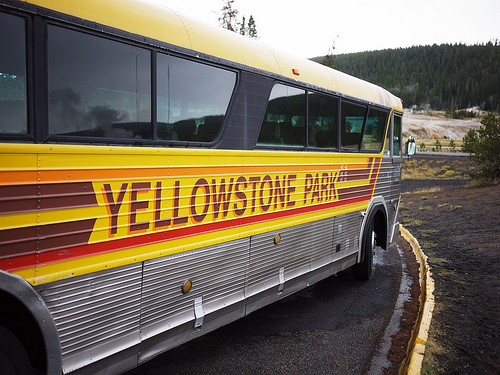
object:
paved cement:
[110, 237, 424, 374]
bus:
[0, 0, 419, 372]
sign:
[101, 170, 341, 235]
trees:
[243, 15, 257, 39]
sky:
[141, 0, 500, 60]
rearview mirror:
[408, 141, 415, 155]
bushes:
[478, 42, 498, 70]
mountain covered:
[307, 41, 500, 113]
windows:
[306, 89, 340, 151]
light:
[181, 278, 194, 295]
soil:
[396, 189, 500, 374]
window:
[47, 17, 154, 143]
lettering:
[96, 171, 342, 235]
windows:
[1, 4, 34, 143]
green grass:
[426, 238, 500, 374]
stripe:
[0, 168, 371, 198]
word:
[102, 174, 297, 236]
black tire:
[355, 224, 375, 278]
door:
[138, 237, 251, 327]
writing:
[99, 170, 340, 236]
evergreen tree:
[429, 45, 449, 68]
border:
[395, 218, 434, 374]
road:
[124, 225, 427, 373]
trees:
[367, 48, 379, 70]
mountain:
[307, 42, 500, 113]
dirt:
[396, 153, 500, 374]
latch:
[192, 295, 204, 329]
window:
[151, 49, 241, 148]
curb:
[397, 221, 439, 375]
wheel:
[358, 208, 379, 280]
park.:
[304, 172, 338, 204]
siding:
[38, 207, 369, 371]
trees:
[474, 42, 487, 68]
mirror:
[402, 135, 417, 161]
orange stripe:
[0, 163, 370, 188]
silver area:
[34, 210, 367, 374]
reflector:
[181, 279, 194, 294]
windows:
[255, 79, 309, 151]